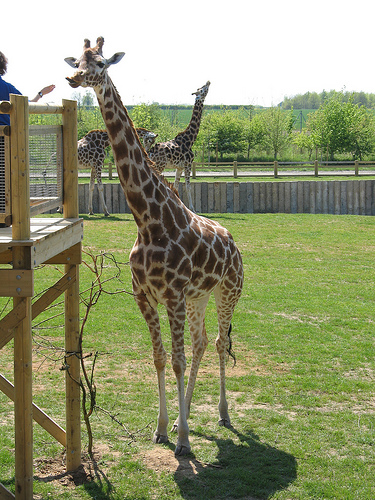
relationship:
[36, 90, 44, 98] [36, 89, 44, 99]
watch on wrist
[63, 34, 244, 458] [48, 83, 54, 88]
giraffe reaching for treat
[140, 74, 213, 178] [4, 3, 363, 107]
giraffe looking to sky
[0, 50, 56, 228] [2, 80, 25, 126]
woman wearing shirt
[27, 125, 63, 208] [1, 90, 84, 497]
mesh on bridge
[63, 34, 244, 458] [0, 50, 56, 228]
giraffe by woman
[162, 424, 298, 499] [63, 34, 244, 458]
shadow of giraffe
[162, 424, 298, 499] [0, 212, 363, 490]
shadow on ground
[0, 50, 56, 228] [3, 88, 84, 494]
woman on platform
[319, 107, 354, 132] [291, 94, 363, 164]
leaves on tree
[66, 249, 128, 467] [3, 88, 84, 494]
branch by platform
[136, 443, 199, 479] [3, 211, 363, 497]
spot in grass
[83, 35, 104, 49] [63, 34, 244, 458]
horns of giraffe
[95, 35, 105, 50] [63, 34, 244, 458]
ear of giraffe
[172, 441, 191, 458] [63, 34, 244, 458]
hoof of giraffe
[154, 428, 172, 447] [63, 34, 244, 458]
hoof of giraffe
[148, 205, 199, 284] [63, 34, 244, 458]
spots on giraffe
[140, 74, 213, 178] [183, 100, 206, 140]
giraffe stretching neck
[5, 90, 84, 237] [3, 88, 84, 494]
railing on platform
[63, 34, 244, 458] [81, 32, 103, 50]
giraffe has ossicones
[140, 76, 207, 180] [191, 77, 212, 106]
giraffe holding head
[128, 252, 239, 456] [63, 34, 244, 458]
legs on giraffe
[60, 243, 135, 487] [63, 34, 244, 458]
tree in front of giraffe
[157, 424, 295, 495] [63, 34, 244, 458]
shadow of giraffe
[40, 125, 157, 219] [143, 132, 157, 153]
giraffe with head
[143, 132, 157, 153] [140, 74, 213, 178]
head on giraffe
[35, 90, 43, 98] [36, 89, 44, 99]
watch on wrist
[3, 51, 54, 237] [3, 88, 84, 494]
woman on platform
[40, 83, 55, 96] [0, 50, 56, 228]
right hand belonging to woman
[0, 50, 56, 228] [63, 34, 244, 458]
woman standing above giraffe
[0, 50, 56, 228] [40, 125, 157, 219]
woman standing above giraffe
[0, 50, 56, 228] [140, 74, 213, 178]
woman standing above giraffe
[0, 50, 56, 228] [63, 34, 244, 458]
woman feeding giraffe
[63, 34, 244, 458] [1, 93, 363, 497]
giraffe standing in zoo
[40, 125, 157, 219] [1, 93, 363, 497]
giraffe standing in zoo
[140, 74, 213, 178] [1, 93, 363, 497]
giraffe standing in zoo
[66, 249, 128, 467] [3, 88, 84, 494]
branch attached to platform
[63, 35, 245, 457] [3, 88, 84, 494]
animal standing next to platform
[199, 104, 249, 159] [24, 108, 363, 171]
tree surrounding field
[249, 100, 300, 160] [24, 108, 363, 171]
tree surrounding field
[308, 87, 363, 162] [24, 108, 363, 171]
tree surrounding field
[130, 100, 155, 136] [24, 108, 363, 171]
tree surrounding field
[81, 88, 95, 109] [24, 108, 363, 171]
tree surrounding field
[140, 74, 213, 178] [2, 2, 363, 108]
giraffe looking up at air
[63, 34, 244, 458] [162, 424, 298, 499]
giraffe casting shadow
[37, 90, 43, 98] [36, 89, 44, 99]
watch worn around wrist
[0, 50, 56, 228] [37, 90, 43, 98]
woman wearing watch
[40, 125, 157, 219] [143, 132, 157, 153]
giraffe rubbing head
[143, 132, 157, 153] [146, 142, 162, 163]
head being rubbed on butt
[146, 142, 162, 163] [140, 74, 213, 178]
butt belonging to giraffe